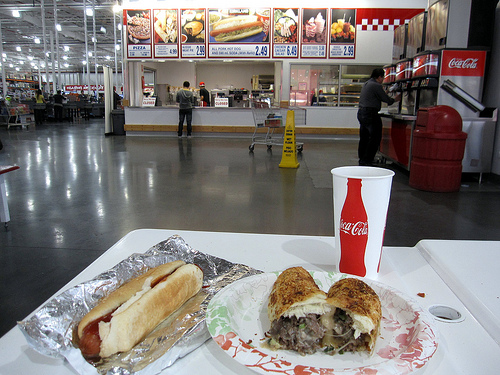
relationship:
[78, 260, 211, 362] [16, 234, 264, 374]
hot dog in aluminum foil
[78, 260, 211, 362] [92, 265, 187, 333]
hot dog with ketchup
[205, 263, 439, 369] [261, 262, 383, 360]
plate with food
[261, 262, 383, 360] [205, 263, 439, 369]
food on plate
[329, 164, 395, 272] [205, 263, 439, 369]
cup next to plate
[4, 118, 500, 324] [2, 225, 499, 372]
floor next to table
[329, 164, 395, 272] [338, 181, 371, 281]
cup with bottle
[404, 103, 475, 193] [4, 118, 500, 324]
trash can on floor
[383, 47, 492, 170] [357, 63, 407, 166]
coke machine next to man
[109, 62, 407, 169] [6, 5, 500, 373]
people in store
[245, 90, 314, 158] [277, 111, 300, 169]
buggy behind caution cone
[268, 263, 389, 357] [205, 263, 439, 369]
sandwich on plate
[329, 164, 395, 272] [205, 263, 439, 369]
cup behind plate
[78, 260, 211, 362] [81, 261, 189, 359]
hot dog in bun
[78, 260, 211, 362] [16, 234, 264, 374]
hot dog on aluminum foil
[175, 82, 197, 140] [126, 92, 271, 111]
person at counter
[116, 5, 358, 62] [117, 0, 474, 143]
menu on wall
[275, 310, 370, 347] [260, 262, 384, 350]
meat inside bread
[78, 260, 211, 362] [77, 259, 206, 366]
hot dog on aluminum foil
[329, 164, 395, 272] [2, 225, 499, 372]
cup on table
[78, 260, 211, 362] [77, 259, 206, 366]
hot dog in aluminum foil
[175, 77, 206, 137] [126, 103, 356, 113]
person standing at counter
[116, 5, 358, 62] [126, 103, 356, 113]
menu over counter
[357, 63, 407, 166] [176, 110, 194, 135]
man in jeans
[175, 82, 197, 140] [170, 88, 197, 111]
person wearing shirt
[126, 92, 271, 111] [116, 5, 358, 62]
counter for food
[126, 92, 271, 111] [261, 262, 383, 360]
counter for food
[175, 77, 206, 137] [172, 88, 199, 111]
person in shirt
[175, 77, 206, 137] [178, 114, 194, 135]
person in jeans